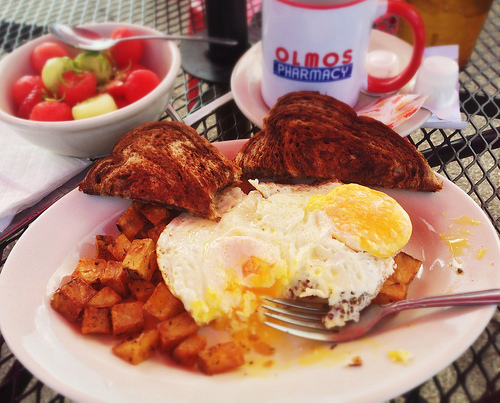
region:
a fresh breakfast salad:
[2, 31, 149, 111]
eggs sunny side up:
[190, 205, 415, 310]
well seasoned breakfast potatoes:
[60, 220, 185, 352]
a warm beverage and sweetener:
[260, 5, 431, 121]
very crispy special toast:
[71, 130, 441, 201]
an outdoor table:
[436, 5, 496, 175]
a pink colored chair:
[175, 5, 255, 55]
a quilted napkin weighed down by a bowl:
[1, 146, 82, 216]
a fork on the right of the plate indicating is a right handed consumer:
[270, 290, 490, 340]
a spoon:
[39, 7, 239, 55]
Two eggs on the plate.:
[176, 180, 494, 308]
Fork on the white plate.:
[249, 279, 495, 359]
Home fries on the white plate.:
[51, 227, 192, 329]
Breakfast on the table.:
[101, 151, 481, 383]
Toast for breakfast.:
[76, 145, 208, 190]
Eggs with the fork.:
[205, 211, 496, 386]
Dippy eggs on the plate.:
[164, 231, 319, 375]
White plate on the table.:
[215, 260, 381, 390]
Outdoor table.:
[440, 150, 485, 195]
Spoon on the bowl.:
[22, 17, 262, 92]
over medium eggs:
[150, 169, 417, 338]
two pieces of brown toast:
[88, 107, 433, 199]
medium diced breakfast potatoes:
[66, 223, 176, 358]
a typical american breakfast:
[60, 102, 425, 374]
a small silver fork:
[263, 286, 499, 336]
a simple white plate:
[3, 118, 497, 392]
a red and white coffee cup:
[246, 4, 426, 121]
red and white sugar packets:
[355, 85, 432, 130]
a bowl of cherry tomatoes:
[1, 12, 175, 114]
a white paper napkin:
[0, 125, 87, 225]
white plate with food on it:
[13, 103, 498, 399]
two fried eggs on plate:
[135, 146, 473, 330]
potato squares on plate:
[45, 178, 260, 396]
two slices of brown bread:
[70, 77, 453, 202]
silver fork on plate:
[240, 275, 496, 338]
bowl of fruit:
[7, 16, 183, 172]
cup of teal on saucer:
[221, 0, 482, 151]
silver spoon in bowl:
[35, 1, 300, 71]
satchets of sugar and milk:
[356, 45, 481, 135]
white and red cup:
[247, 0, 455, 107]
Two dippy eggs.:
[186, 177, 475, 312]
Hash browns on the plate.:
[61, 226, 231, 322]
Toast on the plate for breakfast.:
[96, 150, 372, 200]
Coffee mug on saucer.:
[255, 15, 445, 130]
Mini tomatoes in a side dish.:
[17, 23, 249, 205]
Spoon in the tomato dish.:
[42, 16, 339, 78]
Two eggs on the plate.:
[180, 200, 492, 250]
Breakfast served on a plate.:
[39, 83, 494, 391]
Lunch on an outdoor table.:
[419, 87, 489, 139]